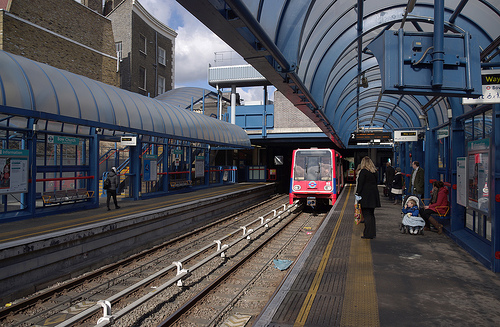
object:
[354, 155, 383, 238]
woman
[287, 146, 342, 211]
train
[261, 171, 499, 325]
ground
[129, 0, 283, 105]
sky